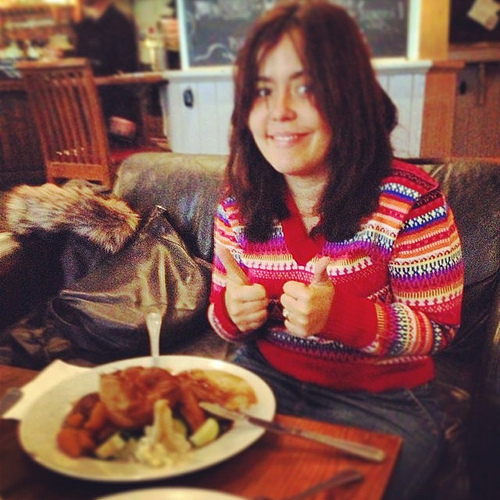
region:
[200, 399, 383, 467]
this is a knife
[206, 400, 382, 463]
the knife is metallic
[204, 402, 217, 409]
the knife is shiny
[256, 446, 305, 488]
this is a table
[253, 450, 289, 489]
the table is wooden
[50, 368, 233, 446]
this is some food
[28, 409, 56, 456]
this is a plate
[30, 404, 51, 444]
the plate is white in color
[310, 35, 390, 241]
the hair is long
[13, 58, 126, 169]
this is a chair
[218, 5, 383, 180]
the head of a woman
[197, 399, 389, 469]
a metal knife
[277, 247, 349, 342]
the hand of the woman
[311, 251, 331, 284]
the thumb of the woman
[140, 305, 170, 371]
the handle of a fork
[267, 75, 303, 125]
the nose of the woman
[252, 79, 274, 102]
the eye of the woman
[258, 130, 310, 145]
the mouth of the woman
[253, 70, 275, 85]
the eyebrow of a woman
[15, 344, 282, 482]
a white plate of food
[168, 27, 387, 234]
a woman with brown hair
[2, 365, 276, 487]
a plate of food on a table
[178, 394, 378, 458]
a silver knife on a plate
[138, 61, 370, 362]
a girl giving the thumbs up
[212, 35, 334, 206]
a girl smiling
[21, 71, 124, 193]
a wooden brown chair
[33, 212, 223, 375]
a purse on a couch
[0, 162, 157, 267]
a jacket with fur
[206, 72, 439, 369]
a girl wearing a multicolored sweater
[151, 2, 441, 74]
a black chalk board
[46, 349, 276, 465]
this is a chicken dinner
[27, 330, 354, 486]
dinner is on the table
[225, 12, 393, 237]
the woman is happy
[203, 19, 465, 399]
the women has two thumbs up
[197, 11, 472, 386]
the girl has a red sweater on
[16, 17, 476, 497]
she is in a restaurant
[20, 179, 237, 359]
the jacket is black with fur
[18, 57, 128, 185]
the chair is wooden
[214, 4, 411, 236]
the woman has brown hair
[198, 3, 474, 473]
the woman is wearing jeans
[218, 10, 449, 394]
this is a lady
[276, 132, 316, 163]
the lady has alight skin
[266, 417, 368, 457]
this is a knife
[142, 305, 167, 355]
this is a spoon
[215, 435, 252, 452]
this is a plate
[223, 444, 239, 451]
the plate is white in color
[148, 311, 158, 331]
the spoon is metallic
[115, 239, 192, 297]
this is a handbag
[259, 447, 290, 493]
this is the table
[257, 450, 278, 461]
the table is wooden